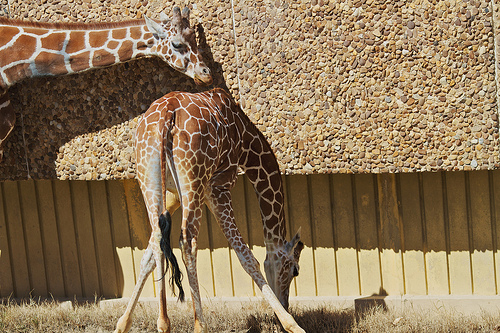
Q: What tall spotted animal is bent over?
A: Giraffe.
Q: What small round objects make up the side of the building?
A: Pebbles.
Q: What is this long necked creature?
A: Giraffe.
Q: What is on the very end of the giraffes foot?
A: Hoof.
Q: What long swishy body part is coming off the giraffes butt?
A: Tail.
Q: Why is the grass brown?
A: It's dead.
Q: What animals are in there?
A: Giraffes.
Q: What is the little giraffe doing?
A: Eating.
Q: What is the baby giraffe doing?
A: Trying to stand.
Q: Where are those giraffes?
A: Maybe in the zoo.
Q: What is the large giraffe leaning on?
A: Wall.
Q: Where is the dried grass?
A: At the corner next to the wall.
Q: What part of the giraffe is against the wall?
A: Neck.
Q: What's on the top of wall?
A: Tiny rocks.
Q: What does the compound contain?
A: Two giraffes.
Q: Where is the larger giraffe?
A: On other side of fence.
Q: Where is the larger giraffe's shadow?
A: Agaisnt the wall.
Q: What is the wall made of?
A: Tan gravel stones.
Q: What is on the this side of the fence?
A: Smaller baby giraffe.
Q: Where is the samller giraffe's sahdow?
A: On the field.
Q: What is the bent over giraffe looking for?
A: Food.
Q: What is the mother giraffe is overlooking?
A: It's child.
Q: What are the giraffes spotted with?
A: White and brown spots.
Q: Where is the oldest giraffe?
A: Left.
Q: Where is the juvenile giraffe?
A: Right.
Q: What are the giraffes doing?
A: Grazing.